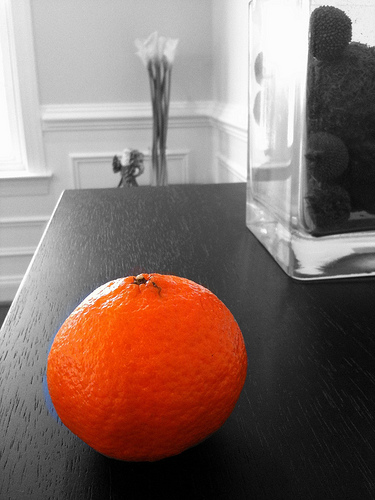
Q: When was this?
A: Daytime.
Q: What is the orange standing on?
A: A table.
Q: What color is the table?
A: Black.